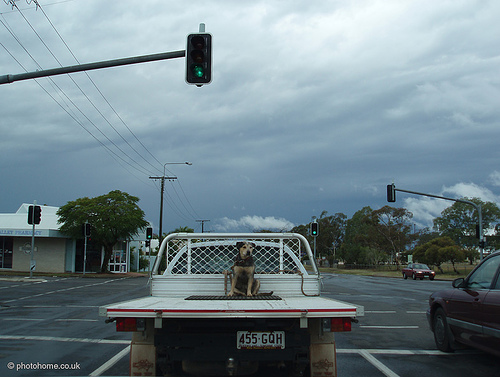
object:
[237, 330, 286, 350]
license plate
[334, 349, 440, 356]
stripe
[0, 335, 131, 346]
stripe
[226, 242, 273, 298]
dog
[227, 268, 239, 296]
leg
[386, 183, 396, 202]
traffic light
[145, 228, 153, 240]
traffic light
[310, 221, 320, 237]
traffic light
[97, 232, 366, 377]
truck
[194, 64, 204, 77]
green signal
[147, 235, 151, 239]
green signal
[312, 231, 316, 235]
green signal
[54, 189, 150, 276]
tree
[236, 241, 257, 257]
dog head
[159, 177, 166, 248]
telephone pole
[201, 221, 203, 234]
telephone pole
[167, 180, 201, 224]
wires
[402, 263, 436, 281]
red car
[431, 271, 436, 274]
headlight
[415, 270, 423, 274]
headlight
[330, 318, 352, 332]
tail light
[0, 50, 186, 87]
pole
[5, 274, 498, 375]
road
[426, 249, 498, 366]
vehicle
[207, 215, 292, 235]
cloud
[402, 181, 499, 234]
cloud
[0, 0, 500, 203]
sky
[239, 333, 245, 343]
numbers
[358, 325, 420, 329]
stripes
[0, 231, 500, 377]
traffic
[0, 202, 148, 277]
building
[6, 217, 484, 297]
view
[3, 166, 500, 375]
intersection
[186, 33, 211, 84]
traffic light